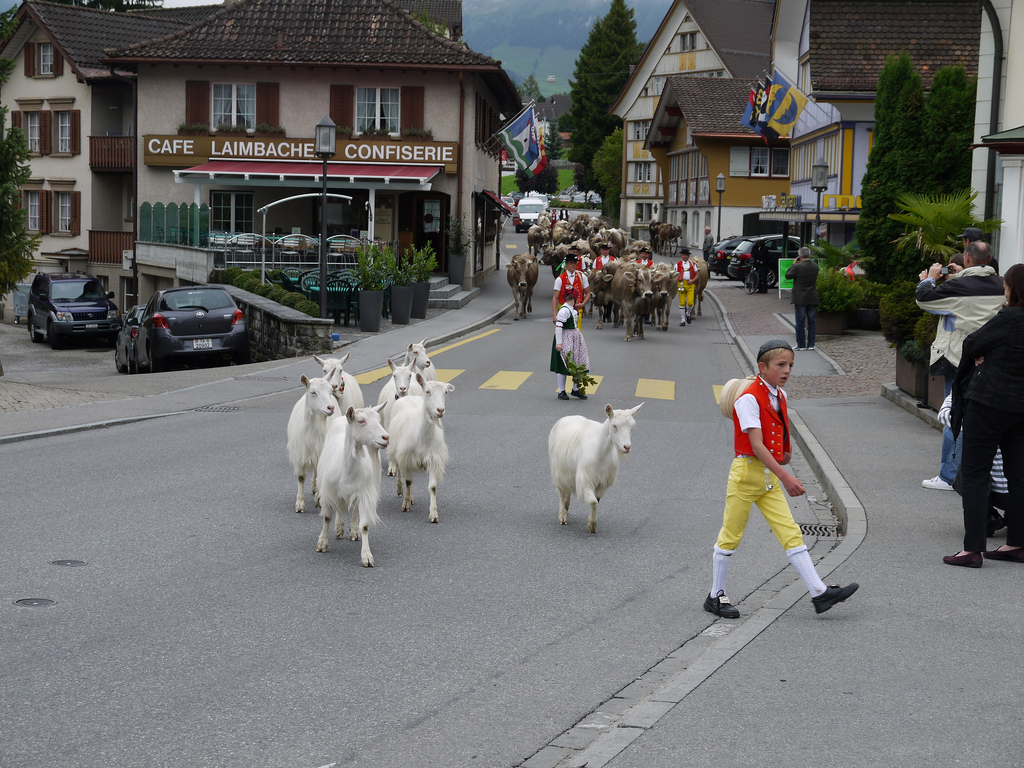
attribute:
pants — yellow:
[719, 454, 815, 565]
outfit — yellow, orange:
[725, 338, 855, 626]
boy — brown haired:
[700, 336, 861, 622]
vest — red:
[734, 368, 791, 462]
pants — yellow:
[723, 452, 817, 552]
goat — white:
[550, 402, 656, 526]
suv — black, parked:
[30, 269, 124, 358]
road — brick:
[8, 322, 246, 407]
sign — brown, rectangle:
[147, 134, 465, 171]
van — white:
[514, 191, 547, 233]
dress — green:
[550, 312, 598, 384]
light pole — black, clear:
[311, 119, 338, 307]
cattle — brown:
[507, 204, 696, 336]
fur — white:
[551, 420, 591, 494]